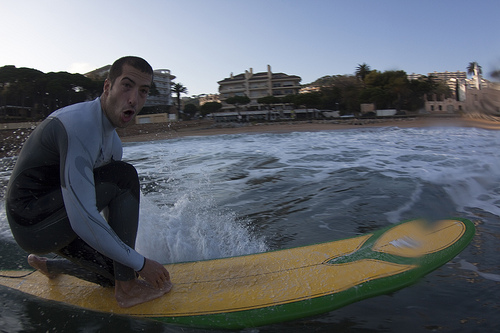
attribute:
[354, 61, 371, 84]
palm tree — tall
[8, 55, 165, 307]
man — surfing, posing, kneeling, crouching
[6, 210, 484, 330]
surfboard — green, yellow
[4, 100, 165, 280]
wetsuit — grey, blue, black, gray, white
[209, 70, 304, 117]
building — beige, tall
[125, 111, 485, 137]
beach — sandy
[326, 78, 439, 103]
trees — green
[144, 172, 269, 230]
bubbles — large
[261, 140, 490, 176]
foam — white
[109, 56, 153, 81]
hair — dark, short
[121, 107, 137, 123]
mouth — open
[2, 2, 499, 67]
sky — clear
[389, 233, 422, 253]
sticker — white